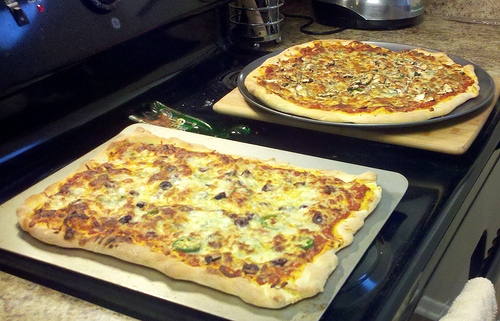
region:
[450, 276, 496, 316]
a white dish towel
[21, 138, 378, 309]
A sicilian pizza with cheese and olives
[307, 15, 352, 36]
A black appliance cord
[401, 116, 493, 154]
The edge of a square wooden cutting board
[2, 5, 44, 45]
A blue light on the stove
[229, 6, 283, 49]
a stainless utensil holder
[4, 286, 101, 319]
a speckled tan counter top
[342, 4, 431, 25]
a stainless and black bottom of an appliance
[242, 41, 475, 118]
a round pizza on a round baking pan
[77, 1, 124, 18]
the bottom of a black knob on the stove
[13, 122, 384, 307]
A baked rectangle pizza.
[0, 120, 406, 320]
A thin baking sheet with a rectangle pizza on it.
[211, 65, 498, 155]
A wood board a round pizza is on.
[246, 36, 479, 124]
A round thick crust pizza.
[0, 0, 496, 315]
The black top of a stove.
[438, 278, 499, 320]
The edge of a white towel on the stove.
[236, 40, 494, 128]
A dark silver round pan.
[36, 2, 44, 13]
A red circle on the top of a stove.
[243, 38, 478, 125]
The brown crust on a round pizza.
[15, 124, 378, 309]
A rectangle crust on a baked pizza.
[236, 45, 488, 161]
Pizza is on a cutting board.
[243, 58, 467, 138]
Pizza is on a round plate.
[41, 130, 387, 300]
Pizza is on a cookie sheet.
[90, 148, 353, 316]
Cheese is on top of a square pizza.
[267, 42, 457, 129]
Cheese is on top of a round pizza.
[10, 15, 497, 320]
Pizza is on top a stove.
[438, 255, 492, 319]
A white towel is draped on the stove.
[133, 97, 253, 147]
A green spoon plate is between two pizzas.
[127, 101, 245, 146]
A spoon plate is on a stove.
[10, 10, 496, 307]
A stove is under two pizzas.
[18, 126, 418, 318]
rectangle pizza on a pizza dish on top of a stove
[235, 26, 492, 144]
round pizza on a pizza tray on top of a wooden board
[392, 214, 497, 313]
part of a black stove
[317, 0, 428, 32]
the bottom part of a kettle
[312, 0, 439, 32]
silver kettle bottom on a kitchen counter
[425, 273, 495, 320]
dish towel hanging on a stove handle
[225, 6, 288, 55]
silver spatular holder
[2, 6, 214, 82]
GE kitchen stove controllers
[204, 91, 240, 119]
kitchen cutting board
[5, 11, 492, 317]
two pizzas sitting on a kitchen stove in pizza trays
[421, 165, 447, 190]
Small black part of the stove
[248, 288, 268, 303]
Light brown crust of the pizza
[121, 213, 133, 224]
Two black olives on the pizza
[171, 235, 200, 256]
Green bell peppers of the pizza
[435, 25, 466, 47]
Brown counter next to stove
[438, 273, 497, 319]
White towel on black stove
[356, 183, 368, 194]
Tomato sauce on the first pizza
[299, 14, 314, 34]
Black cord of the toaster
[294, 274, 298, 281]
Orange cheese on the pizza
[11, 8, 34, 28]
Black switch on the stove